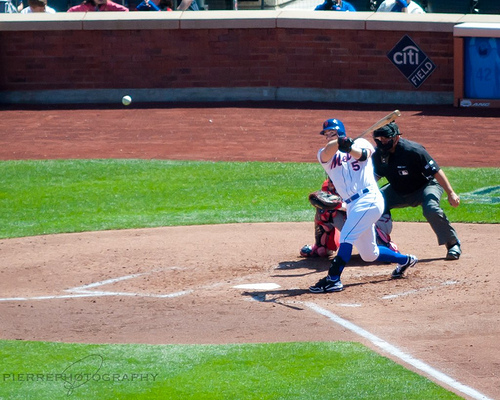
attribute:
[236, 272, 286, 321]
plate — white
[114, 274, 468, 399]
lines — white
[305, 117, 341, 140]
helmet — blue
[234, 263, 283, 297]
plate — white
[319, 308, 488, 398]
line — white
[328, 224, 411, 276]
socks — blue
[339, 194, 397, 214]
belt — blue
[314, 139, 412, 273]
uniform — white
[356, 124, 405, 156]
facemask — blue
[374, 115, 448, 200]
shirt — black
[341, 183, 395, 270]
pants — white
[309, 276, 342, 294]
athletic shoe — black and white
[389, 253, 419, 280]
athletic shoe — black and white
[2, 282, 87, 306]
foul line — white marked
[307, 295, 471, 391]
foul line — white marked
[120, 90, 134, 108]
baseball — in flight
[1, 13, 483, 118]
wall — brick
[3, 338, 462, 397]
grass — green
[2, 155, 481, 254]
grass — green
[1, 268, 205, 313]
line — white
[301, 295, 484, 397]
line — white